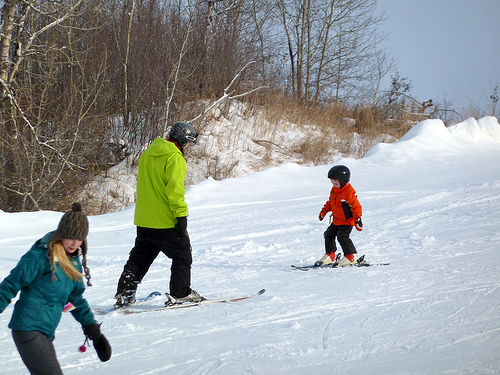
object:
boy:
[318, 164, 363, 265]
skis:
[325, 261, 392, 270]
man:
[113, 120, 202, 308]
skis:
[116, 286, 266, 315]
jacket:
[128, 136, 189, 232]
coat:
[320, 183, 362, 227]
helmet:
[327, 163, 350, 187]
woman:
[1, 202, 113, 374]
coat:
[1, 229, 104, 337]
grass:
[296, 133, 334, 166]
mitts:
[351, 218, 363, 233]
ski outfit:
[316, 180, 365, 256]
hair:
[50, 240, 85, 282]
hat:
[47, 201, 91, 287]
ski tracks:
[0, 178, 499, 374]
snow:
[0, 95, 498, 374]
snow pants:
[320, 223, 357, 255]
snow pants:
[116, 225, 193, 299]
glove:
[78, 322, 112, 361]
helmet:
[167, 118, 199, 149]